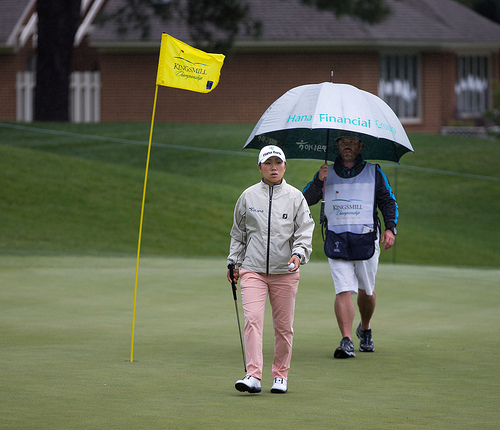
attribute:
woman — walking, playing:
[227, 145, 317, 394]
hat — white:
[259, 144, 287, 168]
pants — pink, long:
[235, 267, 295, 382]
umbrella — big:
[242, 68, 413, 242]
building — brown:
[0, 2, 499, 137]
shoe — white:
[236, 373, 265, 397]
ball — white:
[289, 262, 294, 270]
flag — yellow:
[127, 31, 229, 365]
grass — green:
[211, 244, 213, 253]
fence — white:
[13, 72, 101, 123]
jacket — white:
[228, 176, 317, 275]